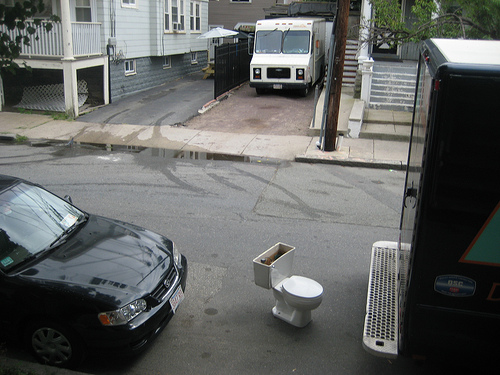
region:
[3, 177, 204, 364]
black car parked on street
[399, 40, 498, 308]
black van parked on street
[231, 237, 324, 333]
white toilet on street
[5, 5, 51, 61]
green leaves on tree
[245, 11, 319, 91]
white van parked in drive way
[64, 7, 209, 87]
gray and white house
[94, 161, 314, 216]
gray colored street pavement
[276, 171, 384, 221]
gray colored street pavement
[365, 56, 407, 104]
gray stairs of house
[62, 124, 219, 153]
tan colored side walk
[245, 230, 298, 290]
The toilet tank has no lid.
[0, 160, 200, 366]
A black car.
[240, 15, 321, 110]
A parked white truck.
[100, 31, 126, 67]
An electrical panel and wiring.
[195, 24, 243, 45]
A large white umbrella.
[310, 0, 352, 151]
A utility pole.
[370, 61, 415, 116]
Front steps.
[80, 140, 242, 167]
A puddle in front of the driveway.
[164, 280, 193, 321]
A license plate.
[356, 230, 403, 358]
A metal bumper.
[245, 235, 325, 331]
white toilet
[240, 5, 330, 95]
parked white delivery truck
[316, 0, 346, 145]
brown leaning utility pole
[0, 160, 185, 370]
partial parked black sedan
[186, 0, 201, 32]
rear window with white frame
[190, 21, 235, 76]
white table umbrella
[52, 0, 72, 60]
support column for front porch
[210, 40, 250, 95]
black 6 foot high iron fence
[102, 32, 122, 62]
electric utility meter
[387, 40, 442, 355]
double rear truck doors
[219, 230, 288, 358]
A toilet bowl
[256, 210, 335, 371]
A toilet bowl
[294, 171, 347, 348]
A toilet bowl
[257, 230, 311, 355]
A toilet bowl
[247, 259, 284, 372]
A toilet bowl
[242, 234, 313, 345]
A toilet bowl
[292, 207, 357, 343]
A toilet bowl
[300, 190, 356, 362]
A toilet bowl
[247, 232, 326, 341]
White ceramic toilet sitting on the street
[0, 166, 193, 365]
Black car parked on the street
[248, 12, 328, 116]
Delivery truck parked in a driveway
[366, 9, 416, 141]
Stairs going up to a house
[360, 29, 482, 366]
Back of a delivery truck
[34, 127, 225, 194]
Puddles of water on the street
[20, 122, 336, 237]
Wet tire tracks on the road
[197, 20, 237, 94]
Picnic table with umbrella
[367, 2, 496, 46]
Top of a tree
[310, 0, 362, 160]
Wood telephone pole in the sidewalk